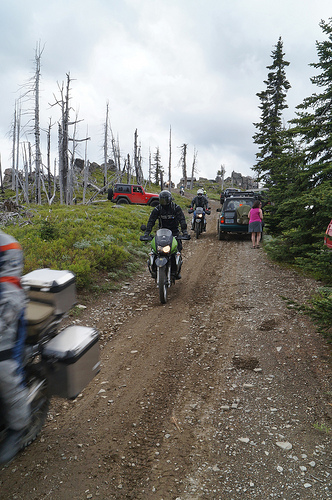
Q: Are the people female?
A: No, they are both male and female.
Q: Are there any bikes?
A: Yes, there is a bike.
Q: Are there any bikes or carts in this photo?
A: Yes, there is a bike.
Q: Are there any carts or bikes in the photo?
A: Yes, there is a bike.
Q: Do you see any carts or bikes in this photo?
A: Yes, there is a bike.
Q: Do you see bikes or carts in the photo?
A: Yes, there is a bike.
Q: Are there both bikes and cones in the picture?
A: No, there is a bike but no cones.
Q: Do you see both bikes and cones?
A: No, there is a bike but no cones.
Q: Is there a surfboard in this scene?
A: No, there are no surfboards.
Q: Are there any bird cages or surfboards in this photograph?
A: No, there are no surfboards or bird cages.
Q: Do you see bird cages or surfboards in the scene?
A: No, there are no surfboards or bird cages.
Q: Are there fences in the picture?
A: No, there are no fences.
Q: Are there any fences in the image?
A: No, there are no fences.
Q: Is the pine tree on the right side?
A: Yes, the pine tree is on the right of the image.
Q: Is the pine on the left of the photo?
A: No, the pine is on the right of the image.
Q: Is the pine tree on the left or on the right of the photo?
A: The pine tree is on the right of the image.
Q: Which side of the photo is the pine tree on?
A: The pine tree is on the right of the image.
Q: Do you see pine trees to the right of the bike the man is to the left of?
A: Yes, there is a pine tree to the right of the bike.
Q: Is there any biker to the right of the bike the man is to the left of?
A: No, there is a pine tree to the right of the bike.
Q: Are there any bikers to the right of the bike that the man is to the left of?
A: No, there is a pine tree to the right of the bike.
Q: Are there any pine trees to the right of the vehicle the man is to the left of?
A: Yes, there is a pine tree to the right of the vehicle.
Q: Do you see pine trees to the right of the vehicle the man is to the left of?
A: Yes, there is a pine tree to the right of the vehicle.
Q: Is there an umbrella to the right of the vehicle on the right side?
A: No, there is a pine tree to the right of the vehicle.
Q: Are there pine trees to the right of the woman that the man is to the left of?
A: Yes, there is a pine tree to the right of the woman.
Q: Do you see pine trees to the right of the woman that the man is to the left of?
A: Yes, there is a pine tree to the right of the woman.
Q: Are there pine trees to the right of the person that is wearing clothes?
A: Yes, there is a pine tree to the right of the woman.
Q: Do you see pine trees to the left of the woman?
A: No, the pine tree is to the right of the woman.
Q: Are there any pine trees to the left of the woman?
A: No, the pine tree is to the right of the woman.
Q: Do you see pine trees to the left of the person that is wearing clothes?
A: No, the pine tree is to the right of the woman.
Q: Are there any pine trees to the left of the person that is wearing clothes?
A: No, the pine tree is to the right of the woman.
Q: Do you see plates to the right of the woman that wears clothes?
A: No, there is a pine tree to the right of the woman.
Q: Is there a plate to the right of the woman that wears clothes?
A: No, there is a pine tree to the right of the woman.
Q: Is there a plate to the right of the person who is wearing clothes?
A: No, there is a pine tree to the right of the woman.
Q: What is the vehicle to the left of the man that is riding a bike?
A: The vehicle is a jeep.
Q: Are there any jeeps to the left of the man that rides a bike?
A: Yes, there is a jeep to the left of the man.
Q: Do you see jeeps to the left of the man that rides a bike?
A: Yes, there is a jeep to the left of the man.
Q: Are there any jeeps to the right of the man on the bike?
A: No, the jeep is to the left of the man.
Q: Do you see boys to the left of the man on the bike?
A: No, there is a jeep to the left of the man.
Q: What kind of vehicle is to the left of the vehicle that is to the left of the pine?
A: The vehicle is a jeep.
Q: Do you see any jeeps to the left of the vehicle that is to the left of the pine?
A: Yes, there is a jeep to the left of the vehicle.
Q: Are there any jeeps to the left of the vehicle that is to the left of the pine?
A: Yes, there is a jeep to the left of the vehicle.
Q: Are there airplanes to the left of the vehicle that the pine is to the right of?
A: No, there is a jeep to the left of the vehicle.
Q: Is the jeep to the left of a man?
A: Yes, the jeep is to the left of a man.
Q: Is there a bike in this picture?
A: Yes, there is a bike.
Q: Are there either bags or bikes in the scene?
A: Yes, there is a bike.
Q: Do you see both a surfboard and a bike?
A: No, there is a bike but no surfboards.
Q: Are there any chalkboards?
A: No, there are no chalkboards.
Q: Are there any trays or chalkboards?
A: No, there are no chalkboards or trays.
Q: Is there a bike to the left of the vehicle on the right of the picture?
A: Yes, there is a bike to the left of the vehicle.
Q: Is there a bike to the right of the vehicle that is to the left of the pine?
A: No, the bike is to the left of the vehicle.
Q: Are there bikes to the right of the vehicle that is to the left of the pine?
A: No, the bike is to the left of the vehicle.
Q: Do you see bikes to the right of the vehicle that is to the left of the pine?
A: No, the bike is to the left of the vehicle.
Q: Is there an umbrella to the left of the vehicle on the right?
A: No, there is a bike to the left of the vehicle.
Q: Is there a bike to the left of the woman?
A: Yes, there is a bike to the left of the woman.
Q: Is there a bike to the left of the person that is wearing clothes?
A: Yes, there is a bike to the left of the woman.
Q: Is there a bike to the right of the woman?
A: No, the bike is to the left of the woman.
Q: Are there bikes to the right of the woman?
A: No, the bike is to the left of the woman.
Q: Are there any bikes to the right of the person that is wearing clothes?
A: No, the bike is to the left of the woman.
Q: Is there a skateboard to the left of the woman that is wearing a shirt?
A: No, there is a bike to the left of the woman.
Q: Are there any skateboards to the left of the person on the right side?
A: No, there is a bike to the left of the woman.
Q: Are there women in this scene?
A: Yes, there is a woman.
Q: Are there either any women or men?
A: Yes, there is a woman.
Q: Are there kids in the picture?
A: No, there are no kids.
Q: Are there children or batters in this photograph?
A: No, there are no children or batters.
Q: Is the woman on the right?
A: Yes, the woman is on the right of the image.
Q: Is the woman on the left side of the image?
A: No, the woman is on the right of the image.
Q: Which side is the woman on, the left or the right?
A: The woman is on the right of the image.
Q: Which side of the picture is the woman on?
A: The woman is on the right of the image.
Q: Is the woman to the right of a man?
A: Yes, the woman is to the right of a man.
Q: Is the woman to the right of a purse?
A: No, the woman is to the right of a man.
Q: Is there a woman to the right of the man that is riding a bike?
A: Yes, there is a woman to the right of the man.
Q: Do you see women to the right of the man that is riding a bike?
A: Yes, there is a woman to the right of the man.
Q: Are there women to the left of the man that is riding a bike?
A: No, the woman is to the right of the man.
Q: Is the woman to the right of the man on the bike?
A: Yes, the woman is to the right of the man.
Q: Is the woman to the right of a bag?
A: No, the woman is to the right of the man.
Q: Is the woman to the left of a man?
A: No, the woman is to the right of a man.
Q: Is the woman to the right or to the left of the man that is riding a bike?
A: The woman is to the right of the man.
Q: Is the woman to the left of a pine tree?
A: Yes, the woman is to the left of a pine tree.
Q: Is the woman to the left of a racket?
A: No, the woman is to the left of a pine tree.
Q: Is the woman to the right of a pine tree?
A: No, the woman is to the left of a pine tree.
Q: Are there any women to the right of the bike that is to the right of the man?
A: Yes, there is a woman to the right of the bike.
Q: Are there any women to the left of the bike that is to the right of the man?
A: No, the woman is to the right of the bike.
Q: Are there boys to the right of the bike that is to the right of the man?
A: No, there is a woman to the right of the bike.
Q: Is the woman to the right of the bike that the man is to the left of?
A: Yes, the woman is to the right of the bike.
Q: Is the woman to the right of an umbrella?
A: No, the woman is to the right of the bike.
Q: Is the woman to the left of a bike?
A: No, the woman is to the right of a bike.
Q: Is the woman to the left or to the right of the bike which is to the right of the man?
A: The woman is to the right of the bike.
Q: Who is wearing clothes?
A: The woman is wearing clothes.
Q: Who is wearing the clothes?
A: The woman is wearing clothes.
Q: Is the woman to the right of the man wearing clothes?
A: Yes, the woman is wearing clothes.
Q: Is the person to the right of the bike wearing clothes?
A: Yes, the woman is wearing clothes.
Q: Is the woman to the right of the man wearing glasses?
A: No, the woman is wearing clothes.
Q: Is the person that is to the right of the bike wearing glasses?
A: No, the woman is wearing clothes.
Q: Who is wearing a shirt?
A: The woman is wearing a shirt.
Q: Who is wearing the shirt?
A: The woman is wearing a shirt.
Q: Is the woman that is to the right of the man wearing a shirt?
A: Yes, the woman is wearing a shirt.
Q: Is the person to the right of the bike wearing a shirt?
A: Yes, the woman is wearing a shirt.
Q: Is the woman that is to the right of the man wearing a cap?
A: No, the woman is wearing a shirt.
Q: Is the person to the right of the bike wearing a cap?
A: No, the woman is wearing a shirt.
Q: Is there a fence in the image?
A: No, there are no fences.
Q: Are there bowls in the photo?
A: No, there are no bowls.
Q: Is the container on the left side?
A: Yes, the container is on the left of the image.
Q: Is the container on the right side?
A: No, the container is on the left of the image.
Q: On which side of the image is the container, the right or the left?
A: The container is on the left of the image.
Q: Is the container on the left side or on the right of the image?
A: The container is on the left of the image.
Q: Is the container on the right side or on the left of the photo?
A: The container is on the left of the image.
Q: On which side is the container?
A: The container is on the left of the image.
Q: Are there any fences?
A: No, there are no fences.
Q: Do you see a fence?
A: No, there are no fences.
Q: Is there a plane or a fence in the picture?
A: No, there are no fences or airplanes.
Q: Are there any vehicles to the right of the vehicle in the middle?
A: Yes, there is a vehicle to the right of the jeep.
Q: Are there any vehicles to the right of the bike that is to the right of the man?
A: Yes, there is a vehicle to the right of the bike.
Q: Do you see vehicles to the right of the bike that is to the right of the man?
A: Yes, there is a vehicle to the right of the bike.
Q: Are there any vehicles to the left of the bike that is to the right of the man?
A: No, the vehicle is to the right of the bike.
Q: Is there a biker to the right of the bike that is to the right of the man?
A: No, there is a vehicle to the right of the bike.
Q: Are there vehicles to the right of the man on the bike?
A: Yes, there is a vehicle to the right of the man.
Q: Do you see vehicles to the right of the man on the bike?
A: Yes, there is a vehicle to the right of the man.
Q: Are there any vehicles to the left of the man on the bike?
A: No, the vehicle is to the right of the man.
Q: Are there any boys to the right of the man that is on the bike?
A: No, there is a vehicle to the right of the man.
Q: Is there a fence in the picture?
A: No, there are no fences.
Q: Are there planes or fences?
A: No, there are no fences or planes.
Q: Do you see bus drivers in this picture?
A: No, there are no bus drivers.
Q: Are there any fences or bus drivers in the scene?
A: No, there are no bus drivers or fences.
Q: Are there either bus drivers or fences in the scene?
A: No, there are no bus drivers or fences.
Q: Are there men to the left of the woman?
A: Yes, there is a man to the left of the woman.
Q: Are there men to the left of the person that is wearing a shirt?
A: Yes, there is a man to the left of the woman.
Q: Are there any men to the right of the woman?
A: No, the man is to the left of the woman.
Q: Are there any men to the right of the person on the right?
A: No, the man is to the left of the woman.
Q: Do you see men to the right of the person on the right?
A: No, the man is to the left of the woman.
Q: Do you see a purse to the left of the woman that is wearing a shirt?
A: No, there is a man to the left of the woman.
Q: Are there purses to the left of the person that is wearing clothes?
A: No, there is a man to the left of the woman.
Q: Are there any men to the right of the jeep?
A: Yes, there is a man to the right of the jeep.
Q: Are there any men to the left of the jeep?
A: No, the man is to the right of the jeep.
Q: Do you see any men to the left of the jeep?
A: No, the man is to the right of the jeep.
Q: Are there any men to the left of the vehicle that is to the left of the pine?
A: Yes, there is a man to the left of the vehicle.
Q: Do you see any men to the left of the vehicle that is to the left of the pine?
A: Yes, there is a man to the left of the vehicle.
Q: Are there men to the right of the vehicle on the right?
A: No, the man is to the left of the vehicle.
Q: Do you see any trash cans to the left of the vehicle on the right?
A: No, there is a man to the left of the vehicle.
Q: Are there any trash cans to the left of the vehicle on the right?
A: No, there is a man to the left of the vehicle.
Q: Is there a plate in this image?
A: No, there are no plates.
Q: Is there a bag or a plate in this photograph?
A: No, there are no plates or bags.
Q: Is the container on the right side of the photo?
A: No, the container is on the left of the image.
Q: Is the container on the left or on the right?
A: The container is on the left of the image.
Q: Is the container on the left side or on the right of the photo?
A: The container is on the left of the image.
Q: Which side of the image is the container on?
A: The container is on the left of the image.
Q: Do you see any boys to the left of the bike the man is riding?
A: No, there is a container to the left of the bike.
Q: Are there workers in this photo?
A: No, there are no workers.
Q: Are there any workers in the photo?
A: No, there are no workers.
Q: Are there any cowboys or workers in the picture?
A: No, there are no workers or cowboys.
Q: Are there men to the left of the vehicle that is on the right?
A: Yes, there is a man to the left of the vehicle.